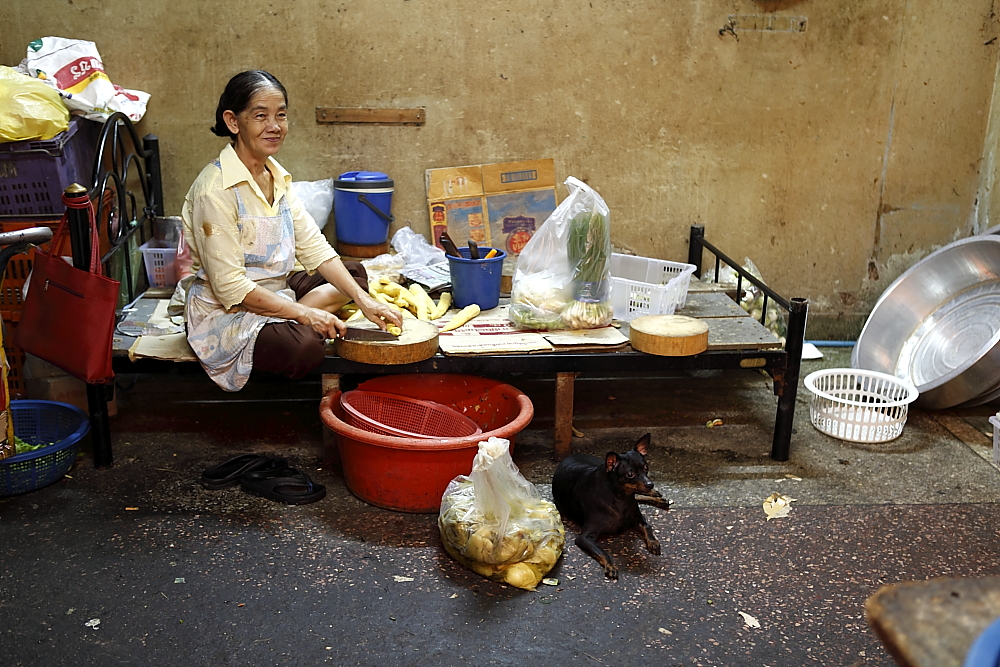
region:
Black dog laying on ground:
[550, 429, 672, 586]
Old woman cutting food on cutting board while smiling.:
[172, 67, 439, 388]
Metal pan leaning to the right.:
[848, 229, 998, 419]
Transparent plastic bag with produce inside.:
[504, 161, 616, 338]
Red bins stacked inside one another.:
[311, 366, 536, 518]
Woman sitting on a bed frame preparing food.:
[65, 69, 807, 469]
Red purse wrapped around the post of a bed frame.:
[12, 117, 163, 464]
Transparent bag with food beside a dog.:
[435, 433, 673, 598]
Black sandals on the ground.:
[188, 441, 335, 513]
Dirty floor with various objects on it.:
[2, 354, 994, 664]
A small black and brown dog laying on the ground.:
[552, 430, 674, 580]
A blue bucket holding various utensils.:
[439, 227, 506, 309]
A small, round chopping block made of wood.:
[625, 307, 713, 358]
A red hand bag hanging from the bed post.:
[11, 180, 121, 384]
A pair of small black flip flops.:
[194, 441, 328, 502]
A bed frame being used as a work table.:
[61, 130, 795, 470]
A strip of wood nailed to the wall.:
[309, 100, 431, 128]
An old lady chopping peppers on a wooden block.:
[169, 69, 439, 381]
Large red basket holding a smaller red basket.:
[319, 366, 536, 513]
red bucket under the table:
[323, 363, 514, 493]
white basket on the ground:
[799, 359, 909, 439]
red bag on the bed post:
[25, 177, 135, 374]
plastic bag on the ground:
[412, 423, 566, 615]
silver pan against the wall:
[829, 213, 999, 378]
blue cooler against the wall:
[322, 153, 397, 240]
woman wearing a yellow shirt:
[152, 127, 320, 299]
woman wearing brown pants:
[257, 314, 318, 379]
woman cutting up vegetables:
[174, 63, 442, 377]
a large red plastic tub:
[312, 361, 534, 511]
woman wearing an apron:
[172, 60, 387, 387]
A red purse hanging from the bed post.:
[36, 169, 130, 379]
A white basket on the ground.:
[816, 347, 893, 454]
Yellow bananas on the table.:
[363, 276, 490, 336]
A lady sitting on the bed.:
[162, 50, 336, 311]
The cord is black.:
[216, 431, 343, 528]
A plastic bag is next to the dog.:
[437, 461, 569, 589]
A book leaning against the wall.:
[443, 141, 560, 265]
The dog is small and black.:
[550, 441, 672, 571]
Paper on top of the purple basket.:
[32, 34, 139, 121]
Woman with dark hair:
[142, 69, 442, 387]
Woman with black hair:
[149, 67, 429, 362]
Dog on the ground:
[526, 439, 733, 583]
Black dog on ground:
[539, 444, 720, 565]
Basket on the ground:
[801, 372, 923, 439]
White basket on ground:
[775, 375, 919, 440]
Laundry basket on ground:
[801, 375, 932, 446]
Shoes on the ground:
[190, 432, 340, 522]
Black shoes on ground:
[195, 440, 325, 510]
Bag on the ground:
[405, 434, 576, 615]